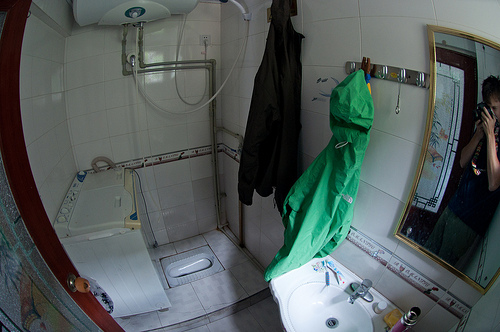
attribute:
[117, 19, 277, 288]
pipes — metal, plumbing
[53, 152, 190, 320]
appliances — white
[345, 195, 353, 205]
brand — white, small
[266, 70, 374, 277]
jacket — green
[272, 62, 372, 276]
jacket — green, hanging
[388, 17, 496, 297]
mirror — gold, framed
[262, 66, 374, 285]
green jacket — light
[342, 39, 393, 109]
pliers — orange, rusted, blue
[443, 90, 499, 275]
man — holding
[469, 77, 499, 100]
hair — brown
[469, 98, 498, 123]
camera — black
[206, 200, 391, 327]
sink — bathroom sink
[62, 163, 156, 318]
appliances — white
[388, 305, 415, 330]
bottle — pink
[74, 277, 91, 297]
cover — orange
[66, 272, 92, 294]
door knob — brass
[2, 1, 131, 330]
door — red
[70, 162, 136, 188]
appliance —  side by side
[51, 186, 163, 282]
appliance —  side by side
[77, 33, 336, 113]
cable plugged — hanging